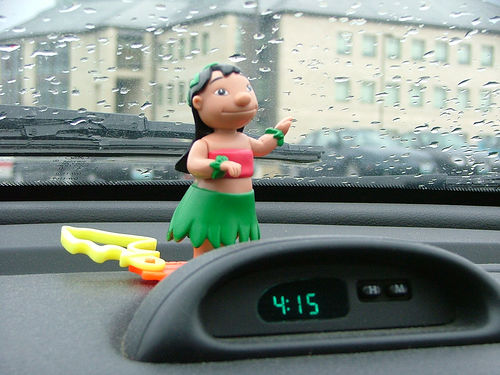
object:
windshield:
[0, 0, 499, 194]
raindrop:
[453, 77, 473, 89]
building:
[0, 0, 499, 142]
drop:
[225, 52, 248, 62]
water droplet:
[104, 65, 120, 73]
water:
[27, 49, 59, 59]